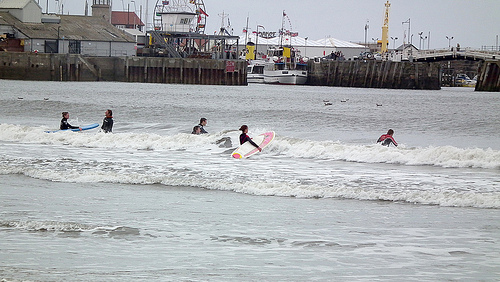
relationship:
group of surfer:
[61, 107, 402, 150] [378, 128, 398, 145]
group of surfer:
[61, 107, 402, 150] [238, 124, 261, 148]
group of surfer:
[61, 107, 402, 150] [191, 127, 203, 134]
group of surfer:
[61, 107, 402, 150] [197, 118, 207, 129]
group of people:
[61, 107, 402, 150] [101, 109, 114, 134]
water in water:
[2, 89, 498, 278] [292, 77, 473, 165]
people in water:
[55, 98, 404, 150] [2, 89, 498, 278]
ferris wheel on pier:
[151, 1, 208, 38] [1, 1, 499, 61]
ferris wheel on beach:
[151, 3, 208, 33] [10, 5, 497, 105]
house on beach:
[5, 10, 156, 58] [10, 5, 497, 105]